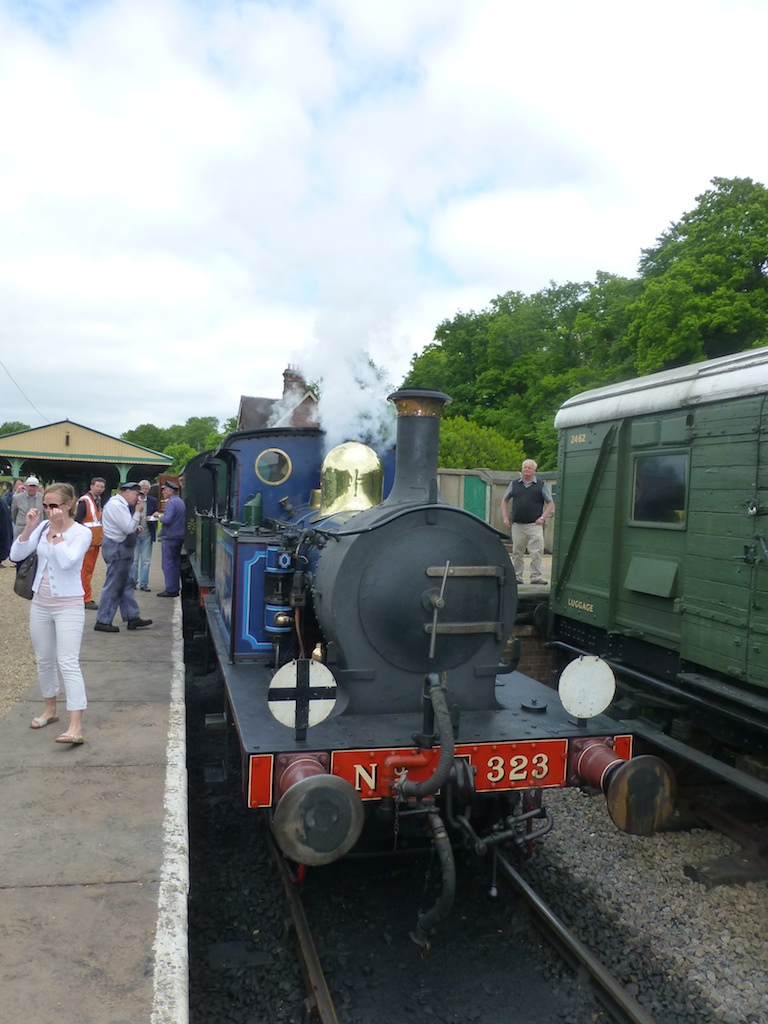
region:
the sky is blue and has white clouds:
[1, 2, 763, 412]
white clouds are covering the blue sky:
[2, 6, 761, 418]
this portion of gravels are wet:
[165, 853, 717, 1021]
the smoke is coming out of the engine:
[187, 222, 680, 949]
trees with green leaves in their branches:
[8, 176, 766, 466]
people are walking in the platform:
[1, 469, 190, 744]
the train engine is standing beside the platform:
[0, 380, 678, 953]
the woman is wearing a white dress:
[5, 481, 94, 744]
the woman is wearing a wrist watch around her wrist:
[10, 480, 94, 744]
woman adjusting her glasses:
[9, 484, 93, 748]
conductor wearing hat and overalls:
[91, 477, 155, 633]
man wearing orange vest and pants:
[74, 476, 106, 610]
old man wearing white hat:
[8, 473, 42, 569]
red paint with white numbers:
[240, 731, 632, 811]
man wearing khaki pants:
[500, 457, 555, 588]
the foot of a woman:
[23, 658, 146, 773]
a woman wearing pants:
[26, 580, 126, 740]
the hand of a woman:
[29, 507, 89, 541]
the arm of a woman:
[10, 436, 132, 593]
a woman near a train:
[28, 490, 407, 751]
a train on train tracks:
[125, 372, 585, 883]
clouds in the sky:
[9, 9, 503, 350]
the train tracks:
[238, 874, 641, 1004]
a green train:
[545, 409, 758, 667]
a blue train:
[183, 410, 654, 863]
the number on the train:
[481, 749, 559, 779]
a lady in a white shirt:
[27, 493, 90, 748]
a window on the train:
[629, 459, 679, 521]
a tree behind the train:
[403, 178, 766, 463]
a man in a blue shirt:
[157, 482, 183, 590]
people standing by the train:
[9, 470, 186, 746]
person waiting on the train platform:
[6, 482, 92, 747]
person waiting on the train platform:
[87, 478, 153, 630]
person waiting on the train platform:
[144, 473, 183, 592]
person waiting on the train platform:
[130, 476, 153, 586]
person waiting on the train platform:
[72, 468, 103, 607]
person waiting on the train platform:
[498, 454, 556, 582]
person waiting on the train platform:
[5, 471, 42, 601]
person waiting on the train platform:
[6, 470, 24, 505]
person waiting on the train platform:
[140, 478, 187, 596]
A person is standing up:
[18, 486, 93, 758]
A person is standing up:
[94, 472, 151, 627]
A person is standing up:
[151, 472, 191, 594]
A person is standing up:
[131, 477, 160, 591]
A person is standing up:
[68, 476, 119, 623]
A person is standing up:
[500, 454, 550, 581]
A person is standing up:
[4, 471, 33, 545]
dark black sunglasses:
[40, 497, 60, 511]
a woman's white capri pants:
[28, 599, 96, 714]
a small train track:
[273, 817, 654, 1022]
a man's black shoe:
[127, 614, 159, 631]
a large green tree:
[588, 172, 766, 394]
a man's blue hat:
[118, 482, 143, 490]